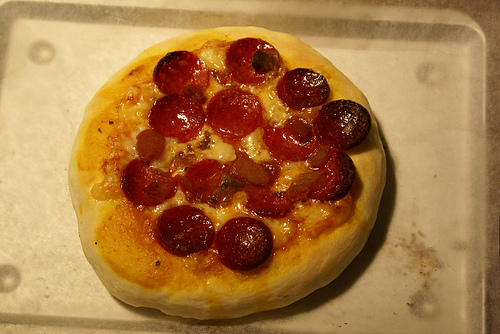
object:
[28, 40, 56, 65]
indention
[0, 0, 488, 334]
pizza pan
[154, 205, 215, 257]
pepperoni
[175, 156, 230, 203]
pepperoni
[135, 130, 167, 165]
onion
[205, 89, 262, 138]
pepperoni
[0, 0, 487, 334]
metal pan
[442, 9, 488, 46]
corner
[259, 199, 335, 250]
cheese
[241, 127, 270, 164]
cheese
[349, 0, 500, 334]
ground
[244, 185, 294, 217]
pepperoni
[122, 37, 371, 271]
pepperoni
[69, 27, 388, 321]
food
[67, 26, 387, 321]
pizza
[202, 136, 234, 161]
cheese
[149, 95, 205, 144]
pepperoni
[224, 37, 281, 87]
pepperoni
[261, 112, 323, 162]
pepperoni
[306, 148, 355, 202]
pepperoni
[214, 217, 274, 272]
pepperoni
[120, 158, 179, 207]
pepperoni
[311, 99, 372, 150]
pepperoni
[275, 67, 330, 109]
pepperoni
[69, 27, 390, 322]
crust